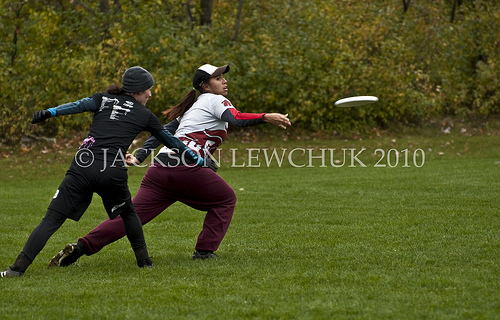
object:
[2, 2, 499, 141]
trees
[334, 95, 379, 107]
frisbee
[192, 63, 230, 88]
cap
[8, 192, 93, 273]
leg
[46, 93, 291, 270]
body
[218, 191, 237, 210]
knee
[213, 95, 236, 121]
sleeve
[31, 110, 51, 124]
glove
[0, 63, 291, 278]
woman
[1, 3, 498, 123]
leaves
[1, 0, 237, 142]
tree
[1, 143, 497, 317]
ground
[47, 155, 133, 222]
shorts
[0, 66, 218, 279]
person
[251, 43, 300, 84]
leaves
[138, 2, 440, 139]
tree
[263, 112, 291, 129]
hand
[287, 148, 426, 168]
writing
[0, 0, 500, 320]
photo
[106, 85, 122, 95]
hair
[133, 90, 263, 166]
shirt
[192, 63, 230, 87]
hat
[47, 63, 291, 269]
girl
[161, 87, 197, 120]
pony tail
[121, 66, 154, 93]
cap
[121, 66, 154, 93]
head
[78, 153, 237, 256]
sweat pants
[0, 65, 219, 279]
woman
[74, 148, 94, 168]
copyright symbol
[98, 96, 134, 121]
letters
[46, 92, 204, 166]
shirt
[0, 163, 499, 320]
grass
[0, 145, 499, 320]
field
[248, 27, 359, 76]
leaves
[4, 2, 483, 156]
trees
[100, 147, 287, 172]
text